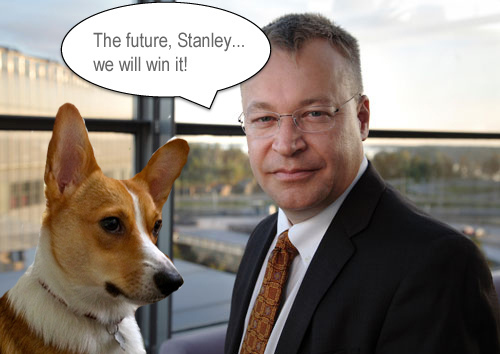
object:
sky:
[0, 0, 500, 148]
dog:
[0, 101, 193, 354]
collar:
[36, 277, 136, 352]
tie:
[238, 228, 301, 354]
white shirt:
[239, 155, 372, 353]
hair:
[258, 12, 360, 63]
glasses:
[236, 92, 364, 139]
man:
[224, 12, 500, 354]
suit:
[224, 153, 500, 353]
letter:
[92, 31, 246, 73]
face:
[241, 52, 363, 208]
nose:
[153, 268, 185, 297]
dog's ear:
[42, 102, 103, 213]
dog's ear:
[133, 137, 190, 214]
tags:
[110, 324, 126, 350]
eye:
[99, 216, 125, 235]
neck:
[25, 262, 137, 336]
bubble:
[58, 0, 271, 111]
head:
[43, 102, 191, 307]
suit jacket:
[351, 228, 446, 338]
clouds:
[414, 17, 481, 118]